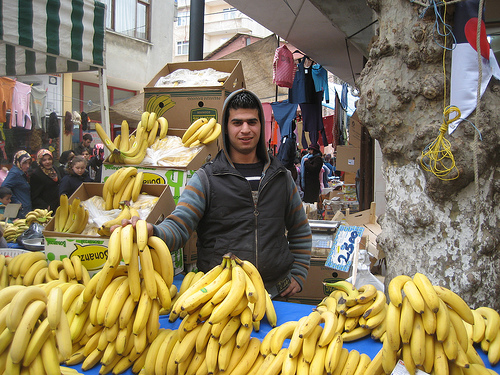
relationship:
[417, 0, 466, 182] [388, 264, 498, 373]
cord hanging over bananas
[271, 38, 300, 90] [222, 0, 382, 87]
clothes hanging from canopy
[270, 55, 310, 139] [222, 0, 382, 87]
clothes hanging from canopy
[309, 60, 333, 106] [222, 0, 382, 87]
clothes hanging from canopy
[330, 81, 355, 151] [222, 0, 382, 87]
clothes hanging from canopy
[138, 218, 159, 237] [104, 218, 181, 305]
hand holding banana bunch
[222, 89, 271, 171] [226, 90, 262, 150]
hood over head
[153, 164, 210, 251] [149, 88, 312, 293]
sleeves on hoodie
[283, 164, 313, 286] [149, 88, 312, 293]
sleeves on hoodie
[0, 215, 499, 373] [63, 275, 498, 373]
bananas on table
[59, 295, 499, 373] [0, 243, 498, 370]
cover on table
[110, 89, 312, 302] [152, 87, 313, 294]
man wearing hoodie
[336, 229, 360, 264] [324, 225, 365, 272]
price on price tag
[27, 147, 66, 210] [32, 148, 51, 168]
woman with scarf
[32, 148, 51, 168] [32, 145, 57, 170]
scarf on head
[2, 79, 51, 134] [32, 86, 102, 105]
clothes on line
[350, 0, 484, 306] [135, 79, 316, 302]
rock on side of person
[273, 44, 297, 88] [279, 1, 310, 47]
clothes on line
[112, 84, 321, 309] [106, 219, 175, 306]
man buying bananas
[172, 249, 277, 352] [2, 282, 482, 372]
banana on table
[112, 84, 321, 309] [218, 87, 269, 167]
man wearing hood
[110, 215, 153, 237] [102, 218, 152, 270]
hand holding banana bunch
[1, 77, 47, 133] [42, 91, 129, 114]
clothes hanging from line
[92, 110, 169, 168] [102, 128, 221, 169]
bananas in box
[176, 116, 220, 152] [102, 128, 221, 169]
bananas in box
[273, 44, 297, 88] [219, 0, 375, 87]
clothes hanging from canopy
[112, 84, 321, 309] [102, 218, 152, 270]
man holding banana bunch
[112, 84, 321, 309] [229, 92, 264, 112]
man with hair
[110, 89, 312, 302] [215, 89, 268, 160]
man with hood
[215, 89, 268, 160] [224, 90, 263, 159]
hood on head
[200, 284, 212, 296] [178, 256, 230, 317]
sticker on banana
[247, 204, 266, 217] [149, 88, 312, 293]
zipper on hoodie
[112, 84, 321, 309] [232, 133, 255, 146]
man with smile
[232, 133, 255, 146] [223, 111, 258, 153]
smile on face